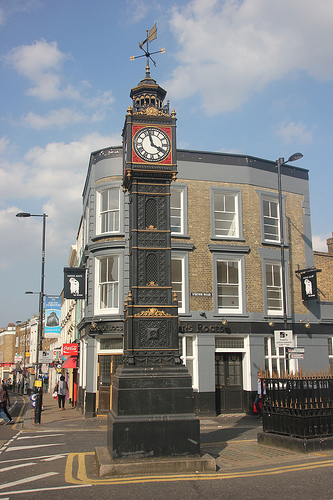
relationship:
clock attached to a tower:
[130, 120, 175, 169] [95, 75, 220, 477]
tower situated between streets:
[95, 75, 220, 477] [0, 417, 332, 499]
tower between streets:
[95, 75, 220, 477] [0, 417, 332, 499]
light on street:
[16, 207, 50, 403] [2, 384, 25, 452]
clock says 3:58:
[130, 120, 175, 169] [146, 127, 169, 159]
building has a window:
[78, 144, 332, 415] [210, 190, 240, 239]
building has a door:
[78, 144, 332, 415] [96, 351, 129, 418]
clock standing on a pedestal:
[130, 120, 175, 169] [92, 443, 219, 475]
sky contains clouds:
[2, 1, 332, 324] [2, 2, 332, 267]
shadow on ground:
[201, 407, 263, 456] [3, 382, 332, 499]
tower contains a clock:
[95, 75, 220, 477] [130, 120, 175, 169]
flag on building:
[64, 265, 85, 299] [78, 144, 332, 415]